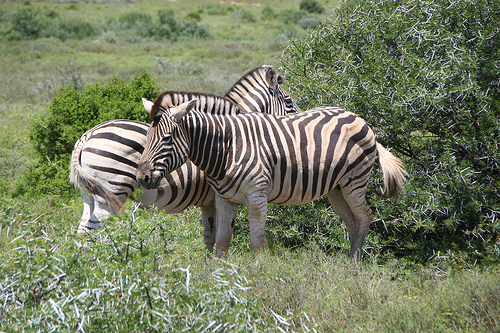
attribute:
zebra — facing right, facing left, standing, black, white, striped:
[134, 90, 412, 260]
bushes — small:
[6, 1, 212, 48]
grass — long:
[1, 198, 321, 331]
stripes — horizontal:
[244, 113, 342, 201]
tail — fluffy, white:
[375, 136, 413, 201]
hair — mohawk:
[148, 90, 240, 119]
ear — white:
[166, 95, 198, 123]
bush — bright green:
[13, 64, 161, 198]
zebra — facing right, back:
[66, 67, 303, 253]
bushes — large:
[229, 0, 484, 267]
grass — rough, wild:
[1, 196, 476, 331]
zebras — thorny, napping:
[67, 63, 411, 260]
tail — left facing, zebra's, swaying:
[374, 140, 414, 199]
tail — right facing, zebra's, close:
[70, 132, 124, 214]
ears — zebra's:
[139, 91, 200, 120]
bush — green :
[384, 55, 470, 253]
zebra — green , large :
[119, 60, 391, 242]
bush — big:
[315, 10, 475, 260]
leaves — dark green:
[239, 20, 478, 229]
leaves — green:
[362, 40, 444, 100]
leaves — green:
[410, 180, 445, 222]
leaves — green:
[410, 100, 443, 142]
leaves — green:
[440, 51, 483, 126]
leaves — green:
[384, 18, 464, 98]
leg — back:
[343, 170, 376, 262]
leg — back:
[330, 190, 355, 247]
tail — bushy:
[376, 131, 413, 202]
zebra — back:
[63, 59, 297, 241]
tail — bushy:
[65, 128, 128, 208]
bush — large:
[268, 7, 480, 260]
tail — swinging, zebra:
[374, 134, 410, 203]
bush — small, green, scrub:
[26, 61, 164, 174]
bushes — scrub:
[10, 4, 215, 39]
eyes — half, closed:
[160, 130, 180, 143]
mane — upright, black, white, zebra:
[150, 89, 251, 115]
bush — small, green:
[15, 159, 66, 203]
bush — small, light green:
[9, 68, 166, 203]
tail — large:
[67, 134, 126, 220]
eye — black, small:
[158, 132, 173, 143]